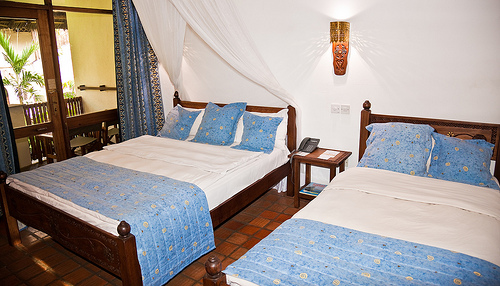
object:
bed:
[2, 90, 299, 285]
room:
[0, 0, 497, 285]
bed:
[201, 99, 499, 286]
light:
[329, 20, 349, 76]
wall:
[157, 5, 497, 191]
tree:
[0, 32, 44, 102]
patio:
[4, 97, 117, 169]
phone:
[298, 136, 321, 153]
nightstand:
[288, 145, 352, 208]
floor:
[1, 184, 315, 286]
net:
[130, 1, 301, 193]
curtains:
[109, 0, 165, 141]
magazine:
[299, 182, 330, 197]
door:
[0, 7, 70, 165]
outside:
[0, 13, 79, 98]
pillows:
[354, 121, 435, 178]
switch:
[330, 105, 351, 115]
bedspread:
[8, 156, 216, 284]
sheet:
[4, 134, 290, 234]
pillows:
[230, 111, 285, 155]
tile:
[0, 187, 309, 285]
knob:
[117, 220, 132, 236]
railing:
[24, 96, 85, 163]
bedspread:
[218, 215, 500, 286]